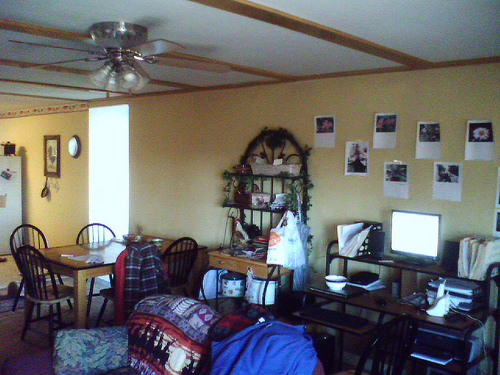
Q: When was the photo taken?
A: Daytime.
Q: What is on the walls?
A: Pictures.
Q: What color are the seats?
A: Black.